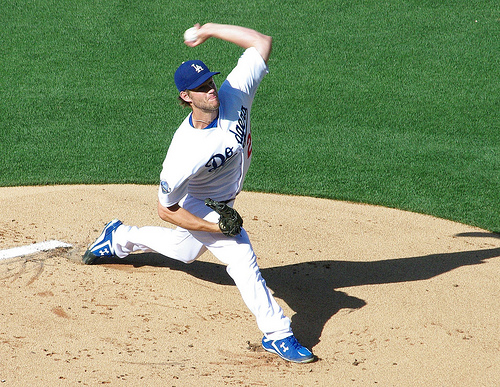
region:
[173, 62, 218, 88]
The hat the player is wearing.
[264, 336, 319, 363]
The left sneaker of the player.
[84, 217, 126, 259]
The right sneaker the player is wearing.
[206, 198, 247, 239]
The black glove the player is wearing.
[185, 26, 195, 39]
The baseball in the player's hand.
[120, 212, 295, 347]
The pants the player is wearing.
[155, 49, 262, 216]
The shirt the player is wearing.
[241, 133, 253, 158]
The number 2 on the player's shirt.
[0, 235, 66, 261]
The base plate behind the player.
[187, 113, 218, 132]
The blue under shirt the player is wearing.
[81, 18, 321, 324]
this is a baseball player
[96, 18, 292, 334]
he is throwing the ball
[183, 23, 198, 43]
the hand is holding a ball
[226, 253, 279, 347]
the leg is in front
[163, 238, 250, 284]
the legs are apart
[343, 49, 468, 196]
this is the pitch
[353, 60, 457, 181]
the grass is green in color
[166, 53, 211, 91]
he is wearing a cap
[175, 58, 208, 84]
the cap is blue in color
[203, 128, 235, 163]
the jersey is white in color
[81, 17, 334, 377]
man wearing a cap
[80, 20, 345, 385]
man wearing white shirt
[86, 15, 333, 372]
man wearing white pants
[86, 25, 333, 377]
man wearing blue shoes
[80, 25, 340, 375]
man holding a glove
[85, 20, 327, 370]
man throwing a ball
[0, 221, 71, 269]
plate on a field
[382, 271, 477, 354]
sand on a field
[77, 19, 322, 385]
man squatting to throw ball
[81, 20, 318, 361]
person is playing baseball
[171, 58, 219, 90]
player has blue hat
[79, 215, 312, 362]
blue and white kleats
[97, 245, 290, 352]
under armour symbol on shoes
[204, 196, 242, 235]
person is holding black mitt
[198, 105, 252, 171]
the shirt says dodgers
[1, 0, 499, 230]
the grass is manicured dark green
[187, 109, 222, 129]
person is wearing blue undershirt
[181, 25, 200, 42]
the baseball is white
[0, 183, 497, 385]
pitcher is standing mound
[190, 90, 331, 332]
This is a player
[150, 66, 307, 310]
This is a baseball player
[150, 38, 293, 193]
This is a hat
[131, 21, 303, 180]
The hat is blue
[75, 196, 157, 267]
This is a shoe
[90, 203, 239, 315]
The shoe is blue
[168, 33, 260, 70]
This is a ball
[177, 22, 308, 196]
The ball is white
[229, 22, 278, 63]
This is an elbow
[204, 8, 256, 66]
This is an arm